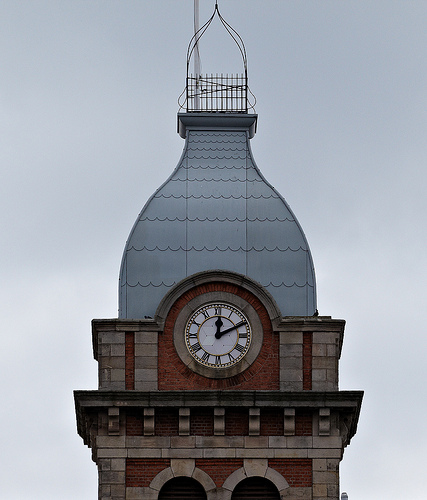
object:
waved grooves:
[184, 129, 251, 160]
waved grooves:
[120, 245, 313, 321]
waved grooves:
[155, 178, 281, 198]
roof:
[176, 111, 258, 139]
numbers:
[189, 307, 248, 364]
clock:
[173, 291, 264, 379]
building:
[72, 0, 364, 499]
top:
[177, 1, 258, 115]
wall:
[175, 181, 245, 258]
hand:
[215, 322, 245, 339]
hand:
[215, 316, 223, 340]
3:
[239, 333, 248, 339]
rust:
[170, 436, 244, 448]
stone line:
[280, 343, 303, 346]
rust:
[193, 361, 242, 379]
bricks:
[311, 332, 337, 391]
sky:
[0, 0, 427, 500]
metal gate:
[185, 72, 248, 113]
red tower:
[72, 281, 364, 500]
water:
[326, 428, 426, 483]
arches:
[148, 464, 287, 499]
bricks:
[247, 358, 279, 390]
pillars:
[280, 331, 340, 390]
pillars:
[98, 331, 159, 390]